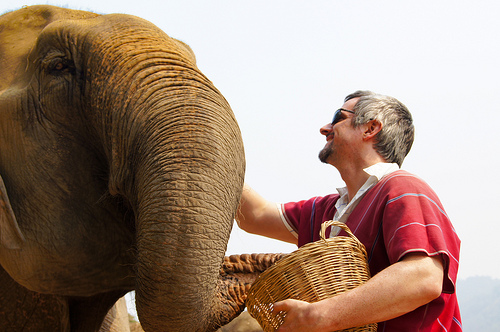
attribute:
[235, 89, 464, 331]
man — happy, smiling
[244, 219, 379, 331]
basket — light brown, wicker, tangible, wooden, brown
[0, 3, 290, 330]
elephant — large, brown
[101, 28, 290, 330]
trunk — brown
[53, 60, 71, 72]
right eye — brown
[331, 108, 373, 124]
sunglasses — black, dark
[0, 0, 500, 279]
sky — clear, hazy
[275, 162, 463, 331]
shirt — red, collared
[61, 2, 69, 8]
hair — small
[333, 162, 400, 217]
collar — white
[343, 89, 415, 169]
hair — graying, grey